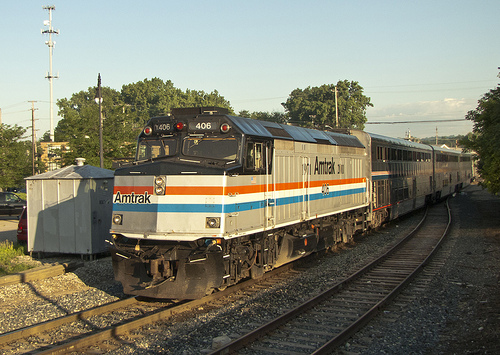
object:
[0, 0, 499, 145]
sky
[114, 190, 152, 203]
black letters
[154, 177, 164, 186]
light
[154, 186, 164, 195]
light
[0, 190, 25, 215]
truck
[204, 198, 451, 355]
tracks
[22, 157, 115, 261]
building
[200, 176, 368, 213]
stripe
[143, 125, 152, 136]
round light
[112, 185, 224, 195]
orange stripe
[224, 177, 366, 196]
orange stripe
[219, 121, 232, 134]
light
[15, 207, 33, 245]
vehicle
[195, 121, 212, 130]
number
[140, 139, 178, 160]
left window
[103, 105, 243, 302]
front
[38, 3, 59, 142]
lights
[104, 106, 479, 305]
train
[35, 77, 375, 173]
trees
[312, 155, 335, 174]
logo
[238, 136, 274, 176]
paint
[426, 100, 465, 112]
clouds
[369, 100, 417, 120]
clouds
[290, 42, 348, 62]
clouds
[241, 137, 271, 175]
window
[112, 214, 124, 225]
headlight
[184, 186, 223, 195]
paint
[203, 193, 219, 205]
paint